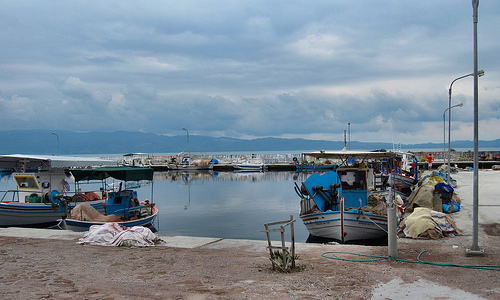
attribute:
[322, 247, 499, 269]
rope — Green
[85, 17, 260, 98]
sky — blue, cloud, cloudy, white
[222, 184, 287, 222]
water — blue, calm, body, next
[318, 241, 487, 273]
hose — green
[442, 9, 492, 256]
pole — grey, tall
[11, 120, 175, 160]
mountain — tall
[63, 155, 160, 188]
green — covering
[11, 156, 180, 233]
boat — white, docked, several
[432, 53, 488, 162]
lamp — gray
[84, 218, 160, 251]
tarp — white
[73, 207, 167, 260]
rag — old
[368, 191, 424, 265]
contraption — metal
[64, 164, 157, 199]
tarp — green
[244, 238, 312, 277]
plant — around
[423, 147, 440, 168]
shirt — red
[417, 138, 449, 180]
person — wearing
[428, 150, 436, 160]
hair — dark